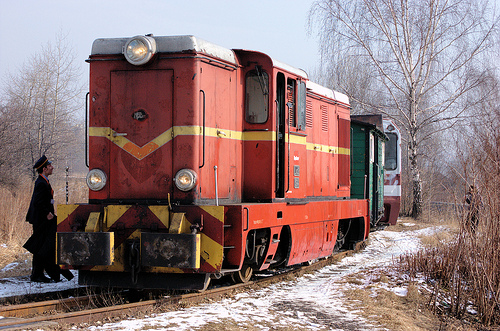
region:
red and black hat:
[28, 140, 50, 176]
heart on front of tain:
[109, 128, 164, 207]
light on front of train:
[163, 161, 201, 195]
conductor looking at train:
[8, 138, 76, 314]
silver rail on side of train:
[184, 80, 216, 180]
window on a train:
[243, 65, 273, 210]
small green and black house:
[340, 108, 397, 255]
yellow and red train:
[70, 203, 227, 288]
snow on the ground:
[290, 238, 404, 329]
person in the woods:
[427, 152, 496, 262]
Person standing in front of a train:
[23, 151, 59, 284]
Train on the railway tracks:
[55, 32, 415, 289]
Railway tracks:
[1, 229, 398, 329]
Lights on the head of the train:
[85, 34, 197, 191]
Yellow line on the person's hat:
[33, 159, 50, 165]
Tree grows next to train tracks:
[305, 0, 498, 219]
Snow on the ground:
[1, 213, 491, 327]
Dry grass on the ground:
[3, 170, 468, 329]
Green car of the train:
[352, 108, 384, 226]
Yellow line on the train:
[88, 125, 351, 162]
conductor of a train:
[12, 134, 72, 293]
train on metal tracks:
[52, 28, 421, 310]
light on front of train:
[110, 31, 175, 69]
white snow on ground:
[269, 282, 344, 324]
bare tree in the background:
[319, 0, 494, 80]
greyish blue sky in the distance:
[9, 4, 296, 32]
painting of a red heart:
[116, 134, 170, 189]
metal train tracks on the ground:
[0, 289, 137, 329]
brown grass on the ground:
[377, 298, 447, 329]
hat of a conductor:
[29, 151, 57, 173]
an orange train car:
[76, 41, 354, 286]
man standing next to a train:
[20, 153, 69, 282]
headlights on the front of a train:
[82, 167, 195, 193]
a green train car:
[353, 113, 388, 217]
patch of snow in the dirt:
[236, 256, 448, 326]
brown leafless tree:
[368, 39, 483, 210]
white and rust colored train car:
[386, 116, 403, 224]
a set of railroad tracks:
[3, 280, 146, 325]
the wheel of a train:
[232, 239, 267, 280]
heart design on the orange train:
[118, 132, 168, 184]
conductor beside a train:
[14, 151, 91, 301]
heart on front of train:
[112, 132, 176, 197]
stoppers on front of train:
[0, 215, 215, 267]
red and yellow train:
[62, 60, 298, 307]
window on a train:
[235, 62, 273, 142]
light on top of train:
[101, 22, 164, 84]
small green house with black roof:
[356, 101, 399, 249]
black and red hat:
[29, 145, 61, 184]